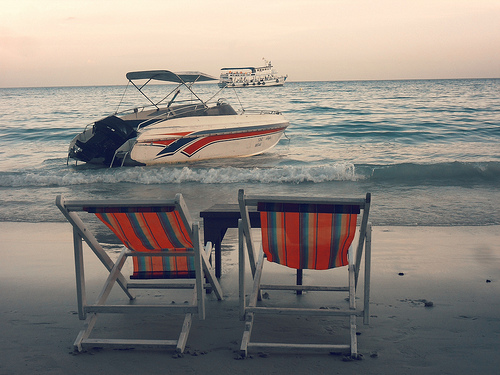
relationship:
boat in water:
[66, 68, 294, 169] [1, 78, 498, 222]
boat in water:
[217, 58, 290, 90] [1, 78, 498, 222]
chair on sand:
[56, 192, 225, 357] [1, 222, 498, 373]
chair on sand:
[232, 188, 375, 358] [1, 222, 498, 373]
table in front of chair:
[200, 201, 262, 295] [56, 192, 225, 357]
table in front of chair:
[200, 201, 262, 295] [232, 188, 375, 358]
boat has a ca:
[66, 68, 294, 169] [125, 69, 231, 84]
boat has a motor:
[66, 68, 294, 169] [66, 115, 137, 165]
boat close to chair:
[66, 68, 294, 169] [56, 192, 225, 357]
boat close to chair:
[66, 68, 294, 169] [232, 188, 375, 358]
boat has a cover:
[66, 68, 294, 169] [125, 69, 231, 84]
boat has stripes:
[66, 68, 294, 169] [135, 126, 285, 160]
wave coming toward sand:
[1, 159, 498, 190] [1, 222, 498, 373]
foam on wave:
[1, 159, 355, 187] [1, 159, 498, 190]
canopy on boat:
[125, 68, 219, 83] [66, 68, 294, 169]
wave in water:
[1, 159, 498, 190] [1, 78, 498, 222]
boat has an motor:
[66, 68, 294, 169] [66, 115, 137, 165]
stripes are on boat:
[135, 126, 285, 160] [66, 68, 294, 169]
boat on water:
[66, 68, 294, 169] [1, 78, 498, 222]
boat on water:
[217, 58, 290, 90] [1, 78, 498, 222]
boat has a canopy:
[66, 68, 294, 169] [125, 68, 219, 83]